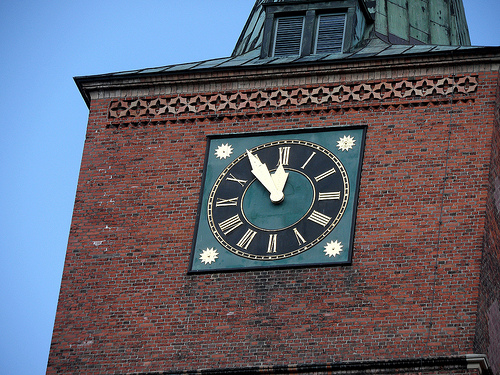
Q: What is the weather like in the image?
A: It is clear.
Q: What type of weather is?
A: It is clear.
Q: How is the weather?
A: It is clear.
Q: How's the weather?
A: It is clear.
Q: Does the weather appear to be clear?
A: Yes, it is clear.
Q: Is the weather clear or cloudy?
A: It is clear.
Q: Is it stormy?
A: No, it is clear.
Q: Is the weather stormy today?
A: No, it is clear.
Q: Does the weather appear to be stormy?
A: No, it is clear.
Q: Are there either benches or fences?
A: No, there are no fences or benches.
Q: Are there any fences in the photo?
A: No, there are no fences.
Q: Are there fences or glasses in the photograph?
A: No, there are no fences or glasses.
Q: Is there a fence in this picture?
A: No, there are no fences.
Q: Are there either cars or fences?
A: No, there are no fences or cars.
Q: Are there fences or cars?
A: No, there are no fences or cars.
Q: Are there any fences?
A: No, there are no fences.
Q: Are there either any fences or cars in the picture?
A: No, there are no fences or cars.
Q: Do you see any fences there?
A: No, there are no fences.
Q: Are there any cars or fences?
A: No, there are no fences or cars.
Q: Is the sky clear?
A: Yes, the sky is clear.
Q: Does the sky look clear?
A: Yes, the sky is clear.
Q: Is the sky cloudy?
A: No, the sky is clear.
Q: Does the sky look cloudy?
A: No, the sky is clear.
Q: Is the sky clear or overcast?
A: The sky is clear.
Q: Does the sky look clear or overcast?
A: The sky is clear.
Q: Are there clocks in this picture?
A: Yes, there is a clock.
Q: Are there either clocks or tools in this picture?
A: Yes, there is a clock.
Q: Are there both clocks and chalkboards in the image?
A: No, there is a clock but no chalkboards.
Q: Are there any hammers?
A: No, there are no hammers.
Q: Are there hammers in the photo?
A: No, there are no hammers.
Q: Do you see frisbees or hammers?
A: No, there are no hammers or frisbees.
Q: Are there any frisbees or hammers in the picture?
A: No, there are no hammers or frisbees.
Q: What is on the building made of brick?
A: The clock is on the building.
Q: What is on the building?
A: The clock is on the building.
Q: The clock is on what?
A: The clock is on the building.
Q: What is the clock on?
A: The clock is on the building.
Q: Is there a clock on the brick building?
A: Yes, there is a clock on the building.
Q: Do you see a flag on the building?
A: No, there is a clock on the building.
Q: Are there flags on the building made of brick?
A: No, there is a clock on the building.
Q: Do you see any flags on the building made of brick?
A: No, there is a clock on the building.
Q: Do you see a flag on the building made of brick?
A: No, there is a clock on the building.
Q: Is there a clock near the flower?
A: Yes, there is a clock near the flower.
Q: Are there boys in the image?
A: No, there are no boys.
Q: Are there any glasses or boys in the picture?
A: No, there are no boys or glasses.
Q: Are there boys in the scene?
A: No, there are no boys.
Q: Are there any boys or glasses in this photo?
A: No, there are no boys or glasses.